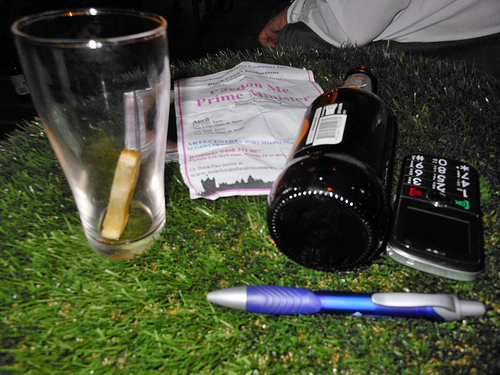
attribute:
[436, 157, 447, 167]
numbers — white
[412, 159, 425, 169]
numbers — white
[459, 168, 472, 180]
numbers — white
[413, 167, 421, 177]
numbers — white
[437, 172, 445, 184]
numbers — white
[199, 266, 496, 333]
pen — blue, laying down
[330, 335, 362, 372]
grass — green, small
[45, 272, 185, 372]
grass patch — patchy, small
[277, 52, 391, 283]
bottle — laying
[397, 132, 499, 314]
phone — black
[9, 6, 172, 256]
tall glass — clear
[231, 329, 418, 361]
grass patch — small, green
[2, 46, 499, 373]
grass — small, green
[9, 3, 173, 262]
glass — clear, small, empty, tall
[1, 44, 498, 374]
green grass — short, small, patchy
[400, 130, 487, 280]
phone — black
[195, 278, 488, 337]
pen — blue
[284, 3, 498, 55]
shirt — white, long sleeved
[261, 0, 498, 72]
person — sitting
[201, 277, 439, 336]
pen — blue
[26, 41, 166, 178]
glass — clar